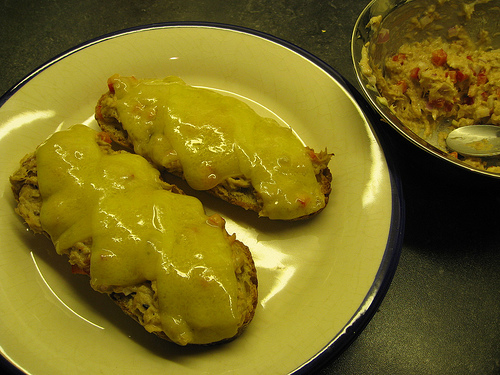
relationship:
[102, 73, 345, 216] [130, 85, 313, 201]
sandwich covered in cheese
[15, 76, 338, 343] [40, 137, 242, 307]
chicken covered in cheese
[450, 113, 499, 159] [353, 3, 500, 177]
spoon in a bowl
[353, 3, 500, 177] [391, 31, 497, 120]
bowl containing filling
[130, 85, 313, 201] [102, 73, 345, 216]
cheese on top of sandwich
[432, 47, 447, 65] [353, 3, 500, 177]
tomato in bowl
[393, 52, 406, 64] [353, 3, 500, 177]
tomato in bowl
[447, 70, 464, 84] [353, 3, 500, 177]
tomato in bowl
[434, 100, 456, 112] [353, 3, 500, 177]
tomato in bowl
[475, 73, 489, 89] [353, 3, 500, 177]
tomato in bowl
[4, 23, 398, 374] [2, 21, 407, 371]
plate has a blue edge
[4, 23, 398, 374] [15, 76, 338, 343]
plate has chicken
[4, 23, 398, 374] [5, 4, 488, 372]
plate on table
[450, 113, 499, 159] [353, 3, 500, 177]
spoon in bowl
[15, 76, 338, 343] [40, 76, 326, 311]
chicken covered in sauce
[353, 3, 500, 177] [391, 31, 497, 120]
pot contains food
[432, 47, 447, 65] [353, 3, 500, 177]
tomatoes in bowl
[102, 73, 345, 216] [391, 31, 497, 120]
sandwich has filling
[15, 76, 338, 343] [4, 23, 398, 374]
chicken on plate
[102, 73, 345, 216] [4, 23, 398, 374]
chicken on a plate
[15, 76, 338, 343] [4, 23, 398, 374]
chicken on a plate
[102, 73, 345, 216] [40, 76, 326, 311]
chicken with sauce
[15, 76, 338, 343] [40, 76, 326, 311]
chicken with sauce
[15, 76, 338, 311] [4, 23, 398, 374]
chicken on plate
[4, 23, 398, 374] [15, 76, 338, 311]
plate with chicken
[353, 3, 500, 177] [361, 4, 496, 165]
bowl containing filling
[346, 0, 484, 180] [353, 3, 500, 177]
edge belonging to bowl